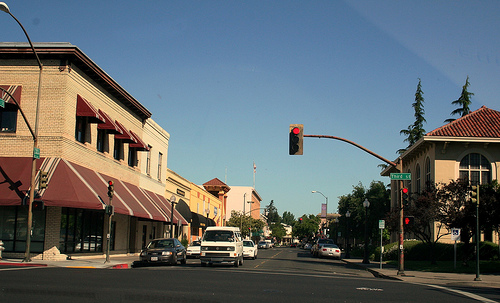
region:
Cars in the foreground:
[128, 218, 261, 284]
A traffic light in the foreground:
[280, 114, 413, 276]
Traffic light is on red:
[282, 116, 307, 161]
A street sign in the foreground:
[375, 165, 418, 183]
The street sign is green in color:
[381, 165, 419, 185]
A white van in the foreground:
[195, 222, 247, 267]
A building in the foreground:
[1, 32, 191, 263]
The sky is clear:
[4, 2, 496, 221]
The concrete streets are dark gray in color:
[0, 245, 498, 301]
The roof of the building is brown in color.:
[373, 103, 498, 179]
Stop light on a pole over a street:
[287, 122, 411, 276]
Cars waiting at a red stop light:
[197, 123, 304, 267]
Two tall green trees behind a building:
[399, 76, 496, 150]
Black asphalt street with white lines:
[0, 267, 498, 300]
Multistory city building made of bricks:
[3, 40, 169, 267]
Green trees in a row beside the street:
[334, 181, 396, 268]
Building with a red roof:
[422, 104, 497, 243]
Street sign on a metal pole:
[387, 154, 412, 274]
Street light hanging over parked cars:
[309, 187, 329, 258]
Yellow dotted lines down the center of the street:
[255, 244, 290, 276]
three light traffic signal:
[285, 122, 307, 158]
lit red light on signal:
[283, 120, 306, 158]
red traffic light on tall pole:
[400, 185, 410, 206]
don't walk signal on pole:
[400, 213, 413, 226]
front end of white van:
[193, 219, 245, 269]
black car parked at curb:
[136, 233, 191, 270]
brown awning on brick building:
[3, 152, 190, 237]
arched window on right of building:
[452, 149, 498, 247]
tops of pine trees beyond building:
[397, 73, 482, 151]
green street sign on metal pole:
[29, 145, 43, 162]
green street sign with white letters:
[390, 171, 409, 178]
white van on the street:
[199, 225, 242, 263]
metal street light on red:
[289, 121, 302, 153]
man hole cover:
[356, 285, 380, 290]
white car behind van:
[241, 237, 257, 257]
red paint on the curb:
[1, 260, 44, 266]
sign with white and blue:
[451, 225, 460, 237]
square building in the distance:
[224, 184, 261, 215]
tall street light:
[310, 188, 328, 240]